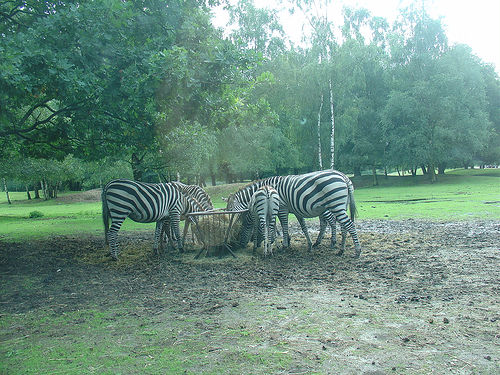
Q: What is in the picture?
A: Zebras.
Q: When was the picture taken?
A: Daytime.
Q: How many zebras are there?
A: Four.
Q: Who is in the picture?
A: Four animals.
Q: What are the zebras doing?
A: Eating.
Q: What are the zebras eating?
A: Hay.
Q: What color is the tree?
A: Green.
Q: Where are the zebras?
A: Under the tree.